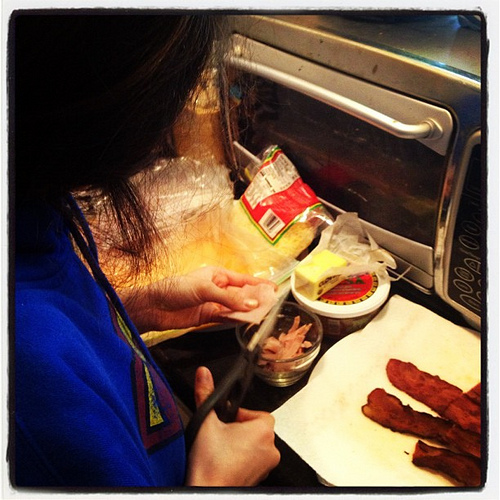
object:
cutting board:
[266, 293, 498, 489]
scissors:
[182, 288, 292, 450]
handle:
[182, 350, 258, 442]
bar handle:
[226, 63, 434, 143]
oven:
[223, 14, 486, 325]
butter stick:
[294, 247, 352, 299]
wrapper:
[293, 211, 396, 299]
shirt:
[16, 196, 190, 497]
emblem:
[109, 303, 187, 450]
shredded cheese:
[227, 244, 253, 269]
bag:
[216, 144, 336, 273]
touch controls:
[449, 151, 493, 318]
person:
[0, 1, 283, 488]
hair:
[1, 2, 218, 316]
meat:
[217, 283, 273, 326]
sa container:
[289, 249, 389, 340]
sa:
[342, 274, 364, 295]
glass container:
[235, 304, 323, 387]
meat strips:
[287, 334, 303, 353]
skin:
[200, 427, 272, 484]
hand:
[186, 365, 280, 489]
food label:
[236, 148, 319, 245]